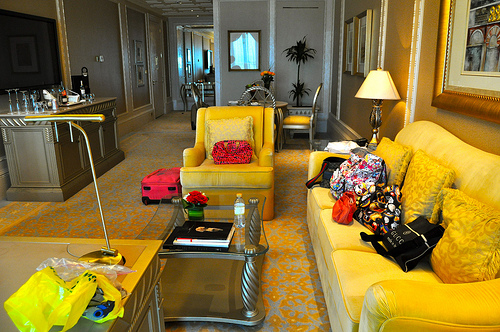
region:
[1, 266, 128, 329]
yellow plastic bag on counter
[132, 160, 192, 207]
pink luggage bag next to yellow chair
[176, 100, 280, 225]
bright yellow chair with pink bag on it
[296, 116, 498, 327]
yellow couch with purses on it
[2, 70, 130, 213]
little side bar in the corner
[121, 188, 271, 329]
glass and metal coffee table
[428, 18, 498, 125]
large golden framed picture on the wall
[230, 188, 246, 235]
water bottle on the table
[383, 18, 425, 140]
reflection of light on the wall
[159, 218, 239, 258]
stack of books on the table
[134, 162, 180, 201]
a red suitcase on the floor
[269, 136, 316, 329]
yellow patterned carpet on the floor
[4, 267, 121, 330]
a yellow plastic bag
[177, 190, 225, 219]
a small vase of flowers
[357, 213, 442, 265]
a black bag on the sofa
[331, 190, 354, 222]
a red purse on the sofa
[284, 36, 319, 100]
a tropical plant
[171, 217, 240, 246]
a stack of magazines on the table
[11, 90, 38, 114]
glasses on the counter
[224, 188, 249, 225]
a bottle of water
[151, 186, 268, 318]
glass coffee table in an apartment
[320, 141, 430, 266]
purses and baggage on a couch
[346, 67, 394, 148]
a side table lamp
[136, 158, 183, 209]
pink suitcase on the floor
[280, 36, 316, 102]
a fake plant against the wall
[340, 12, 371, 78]
artwork hanging on a wall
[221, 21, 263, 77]
a mirror hanging on the wall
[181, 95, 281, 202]
a comfortable chair to sit in with a pillow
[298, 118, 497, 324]
a couch in the living room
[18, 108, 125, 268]
a gold colored desk lap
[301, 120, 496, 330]
yellow leather sofa seat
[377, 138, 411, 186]
yellow pillow on sofa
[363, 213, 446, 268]
black bag on sofa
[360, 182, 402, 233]
black and gold bag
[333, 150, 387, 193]
floral bag on sofa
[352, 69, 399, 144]
lamp sitting on end table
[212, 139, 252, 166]
red and black bag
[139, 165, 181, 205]
red suitcase on floor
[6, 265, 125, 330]
yellow bag on table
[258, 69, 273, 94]
orange flowers in vase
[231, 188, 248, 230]
A bottle on a table.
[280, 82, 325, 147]
A chair with a yellow seat.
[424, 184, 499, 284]
A yellow pillow on the couch.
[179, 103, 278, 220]
A yellow comfy chair.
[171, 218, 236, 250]
A book on the table.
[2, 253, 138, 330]
Paper and plastic on a counter.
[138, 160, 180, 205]
A suitcase on the floor.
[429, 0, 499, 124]
A picture on the wall.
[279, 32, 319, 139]
A plant in a white pot.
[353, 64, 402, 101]
A white lamp shade.